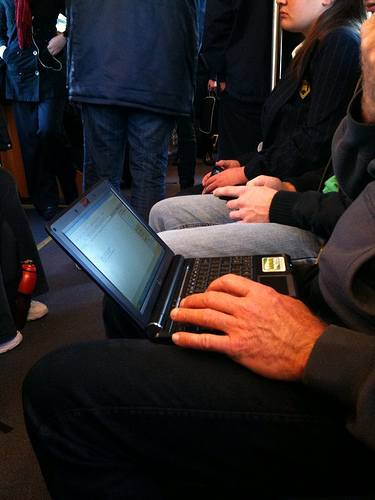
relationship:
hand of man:
[169, 265, 327, 386] [17, 10, 375, 500]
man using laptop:
[17, 10, 375, 500] [62, 168, 306, 283]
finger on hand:
[171, 330, 230, 353] [169, 265, 327, 386]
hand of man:
[169, 265, 327, 386] [31, 16, 373, 487]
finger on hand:
[175, 291, 239, 312] [169, 265, 327, 386]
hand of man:
[169, 265, 327, 386] [214, 124, 360, 343]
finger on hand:
[207, 268, 252, 297] [169, 265, 327, 386]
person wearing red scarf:
[5, 3, 77, 211] [17, 1, 30, 49]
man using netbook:
[17, 10, 375, 500] [44, 181, 307, 344]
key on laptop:
[189, 257, 210, 286] [48, 157, 300, 325]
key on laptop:
[186, 248, 242, 303] [34, 174, 345, 363]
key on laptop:
[189, 257, 210, 286] [50, 151, 293, 337]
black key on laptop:
[188, 253, 257, 276] [42, 157, 299, 345]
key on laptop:
[189, 257, 210, 286] [41, 199, 316, 372]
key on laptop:
[189, 257, 210, 286] [42, 157, 299, 345]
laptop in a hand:
[42, 157, 299, 345] [169, 265, 327, 386]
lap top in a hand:
[42, 176, 299, 343] [169, 265, 327, 386]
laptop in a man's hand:
[42, 157, 299, 345] [174, 273, 300, 365]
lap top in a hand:
[42, 176, 299, 343] [165, 265, 340, 386]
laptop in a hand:
[42, 157, 299, 345] [164, 264, 329, 371]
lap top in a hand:
[54, 180, 300, 336] [169, 265, 327, 386]